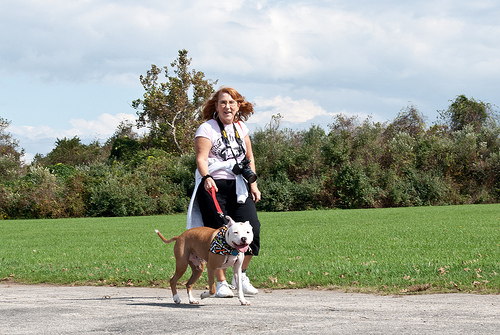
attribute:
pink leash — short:
[208, 189, 225, 214]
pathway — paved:
[1, 283, 494, 330]